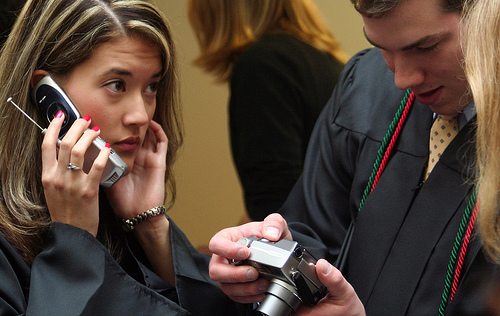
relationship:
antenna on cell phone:
[6, 96, 61, 147] [26, 75, 126, 187]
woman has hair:
[3, 4, 219, 314] [1, 2, 178, 244]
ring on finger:
[66, 163, 79, 176] [67, 129, 100, 174]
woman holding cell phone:
[3, 4, 219, 314] [26, 75, 126, 187]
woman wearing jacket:
[3, 4, 219, 314] [1, 224, 240, 313]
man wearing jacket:
[273, 49, 498, 315] [1, 224, 240, 313]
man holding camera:
[273, 49, 498, 315] [237, 238, 328, 315]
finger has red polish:
[67, 129, 100, 174] [93, 125, 97, 130]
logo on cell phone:
[36, 94, 48, 105] [26, 75, 126, 187]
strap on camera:
[292, 275, 323, 308] [237, 238, 328, 315]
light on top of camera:
[269, 238, 277, 244] [237, 238, 328, 315]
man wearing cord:
[273, 49, 498, 315] [360, 93, 477, 315]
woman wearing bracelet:
[3, 4, 219, 314] [120, 203, 171, 234]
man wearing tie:
[273, 49, 498, 315] [425, 113, 458, 181]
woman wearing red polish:
[3, 4, 219, 314] [93, 125, 97, 130]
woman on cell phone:
[3, 4, 219, 314] [26, 75, 126, 187]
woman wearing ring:
[3, 4, 219, 314] [66, 163, 79, 176]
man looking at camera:
[273, 49, 498, 315] [237, 238, 328, 315]